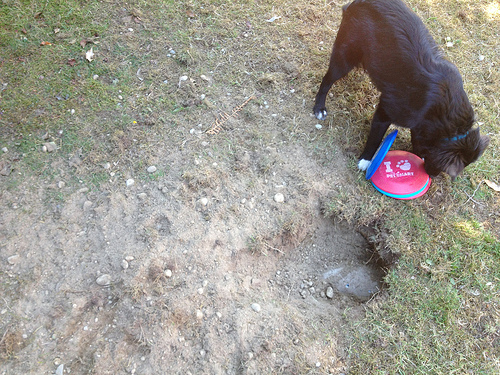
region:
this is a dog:
[309, 3, 494, 198]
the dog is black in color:
[383, 45, 418, 78]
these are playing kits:
[371, 158, 421, 193]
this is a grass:
[9, 13, 31, 29]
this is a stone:
[275, 191, 282, 198]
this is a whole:
[288, 235, 372, 293]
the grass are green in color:
[20, 72, 46, 91]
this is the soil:
[106, 232, 131, 254]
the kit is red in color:
[388, 178, 415, 191]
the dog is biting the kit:
[413, 151, 437, 183]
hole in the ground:
[267, 185, 416, 337]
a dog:
[312, 4, 492, 182]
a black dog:
[311, 3, 486, 179]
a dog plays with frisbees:
[315, 2, 491, 202]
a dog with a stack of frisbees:
[313, 3, 491, 208]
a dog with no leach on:
[303, 3, 485, 209]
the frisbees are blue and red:
[364, 119, 446, 204]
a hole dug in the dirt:
[208, 176, 423, 336]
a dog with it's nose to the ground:
[316, 6, 493, 218]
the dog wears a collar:
[306, 8, 491, 217]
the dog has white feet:
[307, 8, 488, 235]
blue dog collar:
[440, 126, 476, 143]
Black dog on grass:
[312, 2, 497, 177]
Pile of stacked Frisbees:
[359, 127, 432, 200]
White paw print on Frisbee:
[393, 157, 416, 173]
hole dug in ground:
[297, 198, 398, 313]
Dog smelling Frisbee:
[390, 113, 492, 189]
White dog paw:
[350, 150, 375, 175]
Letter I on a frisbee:
[384, 160, 394, 173]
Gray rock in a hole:
[320, 281, 336, 303]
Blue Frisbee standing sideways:
[361, 128, 397, 182]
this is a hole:
[267, 210, 389, 316]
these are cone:
[362, 131, 436, 206]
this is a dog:
[301, 2, 493, 184]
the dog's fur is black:
[430, 92, 450, 157]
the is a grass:
[0, 0, 62, 96]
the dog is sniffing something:
[347, 89, 489, 202]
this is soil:
[78, 229, 208, 337]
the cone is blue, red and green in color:
[369, 137, 431, 205]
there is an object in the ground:
[321, 252, 376, 301]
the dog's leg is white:
[353, 145, 375, 178]